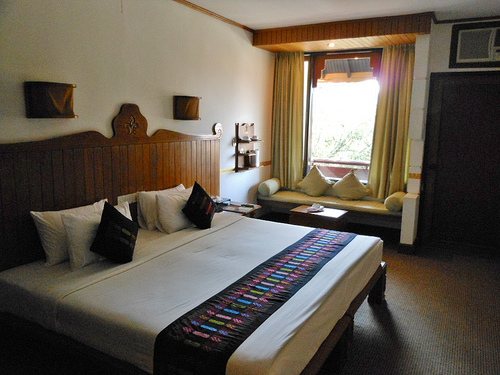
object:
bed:
[1, 103, 387, 374]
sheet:
[0, 206, 384, 373]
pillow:
[34, 198, 110, 269]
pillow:
[61, 200, 136, 270]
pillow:
[137, 180, 187, 232]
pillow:
[182, 181, 217, 229]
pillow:
[91, 202, 142, 265]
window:
[308, 51, 381, 181]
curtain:
[270, 49, 306, 191]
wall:
[1, 1, 276, 223]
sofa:
[246, 173, 407, 244]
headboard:
[1, 103, 221, 273]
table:
[222, 199, 262, 215]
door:
[416, 69, 500, 253]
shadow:
[316, 318, 410, 374]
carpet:
[252, 206, 500, 375]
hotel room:
[1, 2, 500, 373]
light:
[23, 79, 76, 118]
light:
[172, 95, 200, 120]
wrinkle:
[154, 294, 193, 324]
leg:
[367, 269, 393, 304]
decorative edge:
[110, 103, 149, 136]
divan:
[258, 177, 283, 197]